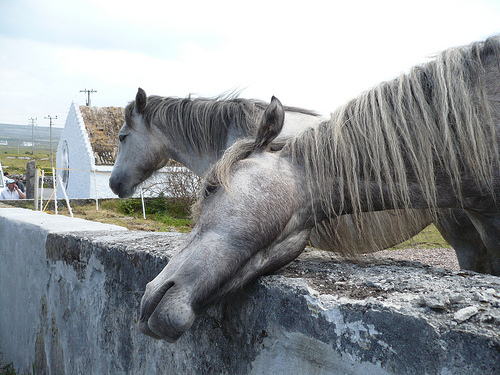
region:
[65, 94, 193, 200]
A horse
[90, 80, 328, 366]
two horses outside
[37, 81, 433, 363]
two horses next to a wall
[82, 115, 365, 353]
A horse laying its head on a wall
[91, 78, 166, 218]
The head of a horse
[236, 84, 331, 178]
The ear of a horse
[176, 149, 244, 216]
The eye of a horse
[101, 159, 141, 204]
The nose of a horse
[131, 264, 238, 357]
The mouth of a horse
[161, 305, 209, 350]
The chin of a horse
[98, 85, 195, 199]
head of a gray mare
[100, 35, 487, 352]
two shaggy gray mares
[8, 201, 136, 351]
old and chipped stone bench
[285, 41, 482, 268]
shaggy straggling mane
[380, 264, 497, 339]
stone chips on a wall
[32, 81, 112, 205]
white church next to horses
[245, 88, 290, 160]
ear of an old gray mare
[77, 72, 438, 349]
two horses at a stone wall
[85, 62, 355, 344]
two gray horse heads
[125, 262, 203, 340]
skinny snout of a gray horse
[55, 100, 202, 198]
white and brown horse stable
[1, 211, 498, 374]
grey stone barrier wall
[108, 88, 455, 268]
large light grey horse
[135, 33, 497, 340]
horse scratching face on wall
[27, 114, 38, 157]
tall wooden electrical pole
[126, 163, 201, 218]
long bare shrub limbs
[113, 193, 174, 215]
small green leaf bush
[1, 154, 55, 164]
asphalt covered country road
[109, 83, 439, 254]
grey horse standing in grass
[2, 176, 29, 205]
man talking on cell phone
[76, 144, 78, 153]
The house is white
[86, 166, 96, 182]
The house is white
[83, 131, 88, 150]
The house is white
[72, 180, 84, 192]
The house is white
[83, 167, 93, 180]
The house is white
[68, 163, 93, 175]
The house is white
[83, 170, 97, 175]
The house is white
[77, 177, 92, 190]
The house is white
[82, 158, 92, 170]
The house is white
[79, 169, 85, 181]
The house is white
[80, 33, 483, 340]
two white horses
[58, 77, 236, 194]
white building with a brown roof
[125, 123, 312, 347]
horse with it's head on conrete barrier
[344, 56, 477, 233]
grey horses man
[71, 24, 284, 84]
white clouds covering sky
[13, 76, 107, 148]
set of three utility poles in the distance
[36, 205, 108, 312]
white paint chipping of concrete barrier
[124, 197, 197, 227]
green grass and bushes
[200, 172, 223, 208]
horse with black eyes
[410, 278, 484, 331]
pieces of concrete breaking off wall